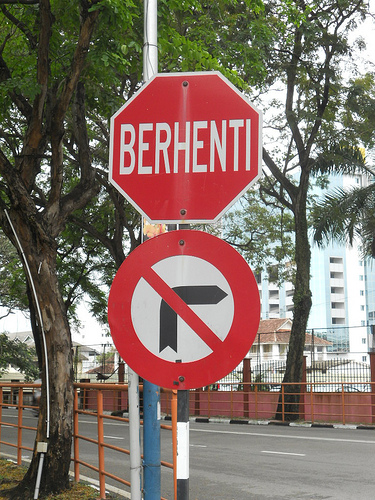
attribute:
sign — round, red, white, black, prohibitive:
[107, 227, 260, 391]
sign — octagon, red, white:
[105, 68, 263, 225]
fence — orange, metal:
[1, 380, 179, 498]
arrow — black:
[156, 284, 229, 352]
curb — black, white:
[1, 403, 372, 432]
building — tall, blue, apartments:
[218, 163, 372, 368]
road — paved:
[2, 409, 374, 498]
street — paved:
[0, 409, 373, 497]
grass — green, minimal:
[2, 453, 127, 499]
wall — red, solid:
[82, 384, 373, 424]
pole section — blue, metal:
[140, 380, 161, 499]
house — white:
[236, 318, 333, 390]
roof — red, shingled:
[253, 316, 334, 349]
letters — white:
[116, 118, 255, 176]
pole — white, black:
[174, 390, 192, 495]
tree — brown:
[3, 2, 286, 499]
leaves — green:
[1, 1, 372, 330]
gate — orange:
[1, 379, 178, 499]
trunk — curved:
[0, 242, 77, 500]